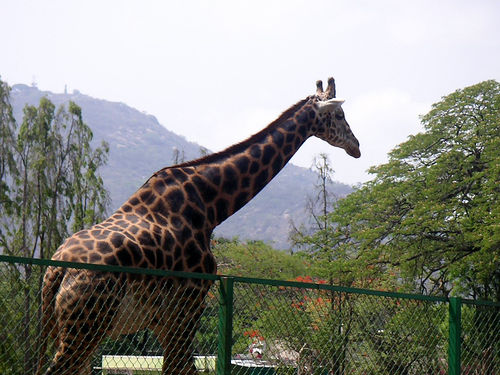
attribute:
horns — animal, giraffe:
[308, 77, 337, 98]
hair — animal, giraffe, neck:
[158, 92, 313, 174]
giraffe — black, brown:
[26, 93, 362, 341]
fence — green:
[10, 259, 468, 370]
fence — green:
[18, 253, 449, 373]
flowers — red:
[296, 262, 346, 316]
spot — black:
[162, 180, 194, 220]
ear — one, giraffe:
[310, 95, 347, 111]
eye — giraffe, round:
[324, 103, 347, 122]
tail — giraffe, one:
[26, 260, 69, 354]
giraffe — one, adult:
[56, 80, 369, 360]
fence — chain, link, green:
[228, 278, 458, 371]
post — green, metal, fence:
[212, 275, 250, 363]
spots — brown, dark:
[119, 201, 194, 261]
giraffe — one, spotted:
[53, 68, 363, 330]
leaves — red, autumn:
[271, 260, 357, 344]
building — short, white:
[224, 317, 305, 373]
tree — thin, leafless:
[287, 156, 357, 273]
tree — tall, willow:
[13, 92, 107, 237]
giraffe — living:
[40, 54, 328, 326]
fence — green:
[183, 251, 453, 372]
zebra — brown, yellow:
[40, 85, 314, 356]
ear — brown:
[306, 71, 376, 143]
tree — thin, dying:
[267, 147, 397, 355]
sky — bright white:
[113, 9, 336, 137]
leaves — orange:
[281, 272, 377, 368]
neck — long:
[148, 95, 357, 251]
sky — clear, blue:
[105, 21, 325, 141]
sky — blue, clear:
[85, 22, 307, 139]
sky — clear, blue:
[159, 25, 321, 146]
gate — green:
[65, 248, 364, 366]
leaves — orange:
[244, 242, 383, 364]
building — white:
[97, 346, 280, 373]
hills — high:
[6, 77, 369, 240]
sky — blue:
[2, 6, 496, 113]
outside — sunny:
[6, 8, 498, 373]